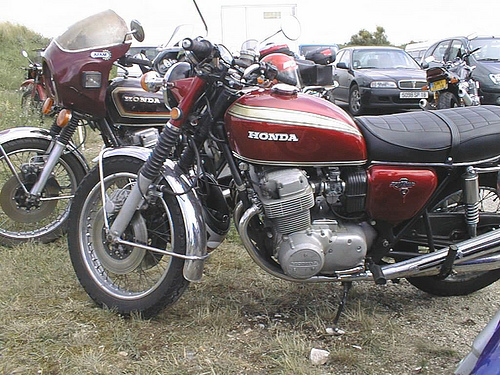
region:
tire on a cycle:
[67, 162, 127, 249]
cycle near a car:
[422, 45, 482, 110]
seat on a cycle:
[355, 102, 493, 152]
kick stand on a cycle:
[322, 292, 352, 323]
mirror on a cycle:
[268, 15, 306, 47]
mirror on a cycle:
[128, 15, 148, 47]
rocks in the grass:
[240, 300, 377, 367]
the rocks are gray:
[370, 286, 472, 364]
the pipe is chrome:
[379, 241, 498, 287]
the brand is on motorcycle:
[240, 126, 315, 170]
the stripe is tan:
[235, 102, 354, 144]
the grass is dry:
[5, 244, 152, 373]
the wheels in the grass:
[2, 141, 192, 319]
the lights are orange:
[38, 100, 81, 130]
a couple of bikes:
[9, 9, 499, 373]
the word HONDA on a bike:
[232, 123, 313, 171]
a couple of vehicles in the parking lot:
[5, 6, 497, 361]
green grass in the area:
[0, 22, 452, 373]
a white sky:
[3, 2, 495, 77]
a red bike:
[52, 22, 497, 323]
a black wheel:
[50, 141, 228, 322]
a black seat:
[329, 85, 497, 176]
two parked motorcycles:
[4, 16, 493, 318]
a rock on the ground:
[303, 346, 336, 366]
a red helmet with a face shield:
[260, 47, 299, 87]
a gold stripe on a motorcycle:
[230, 101, 362, 131]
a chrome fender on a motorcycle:
[89, 145, 214, 287]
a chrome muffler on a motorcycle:
[380, 228, 498, 280]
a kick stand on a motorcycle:
[328, 278, 363, 330]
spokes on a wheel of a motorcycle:
[146, 203, 176, 278]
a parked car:
[325, 32, 430, 117]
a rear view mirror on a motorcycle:
[258, 12, 303, 49]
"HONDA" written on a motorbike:
[243, 126, 301, 145]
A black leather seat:
[353, 104, 498, 164]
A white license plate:
[397, 86, 432, 100]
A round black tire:
[62, 154, 192, 320]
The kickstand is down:
[328, 281, 356, 330]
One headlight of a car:
[365, 75, 402, 92]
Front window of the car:
[348, 44, 424, 67]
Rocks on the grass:
[234, 307, 353, 367]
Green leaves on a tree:
[335, 24, 402, 50]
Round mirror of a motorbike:
[119, 17, 148, 50]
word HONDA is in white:
[248, 130, 300, 142]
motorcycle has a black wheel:
[65, 156, 184, 311]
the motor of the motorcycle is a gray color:
[238, 165, 372, 281]